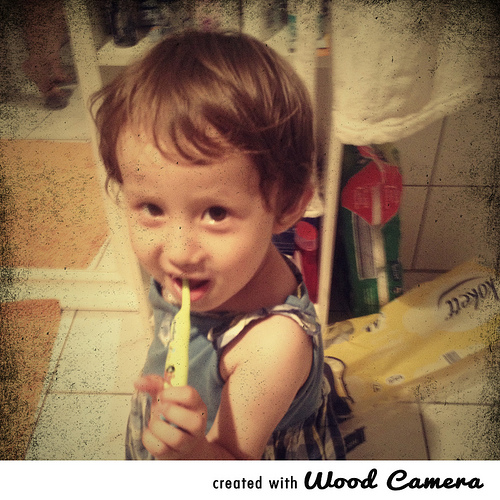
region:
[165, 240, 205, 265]
The nose of the child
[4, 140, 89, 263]
A rug on the floor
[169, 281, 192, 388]
A toothbrush in the child's mouth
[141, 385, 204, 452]
The left hand of the child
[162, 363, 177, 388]
A cartoon character on the toothbrush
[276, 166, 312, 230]
The left ear of the child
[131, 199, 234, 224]
The eyes of the child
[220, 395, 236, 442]
A shadow on the child's arm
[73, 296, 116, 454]
The floor is tiled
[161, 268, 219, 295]
The mouth of the child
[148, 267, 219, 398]
A yellow toothbrush in the girl's mouth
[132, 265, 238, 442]
The girl is holding a yellow toothbrush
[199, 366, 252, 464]
A small shadow on the girl's arm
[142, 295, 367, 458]
A blue and white dress on the girl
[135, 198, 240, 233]
The small girl's brown eyes are open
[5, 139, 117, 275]
Small orange rug behind the girl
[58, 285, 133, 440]
A white tile floor beneath the young girl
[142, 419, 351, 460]
A checkered pattern on the blue and white dress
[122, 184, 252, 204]
The girl's eyebrows can hardly be seen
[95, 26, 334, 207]
The girl's hair is short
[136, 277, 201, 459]
yellow tooth brush in hand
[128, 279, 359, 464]
blue cotton and denim dress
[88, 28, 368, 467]
girl brushing teeth in bathroom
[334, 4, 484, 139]
white towel on rack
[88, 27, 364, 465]
girl standing in bathroom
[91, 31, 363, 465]
girl wearing blue dress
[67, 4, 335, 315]
white plastic shelf in bathroom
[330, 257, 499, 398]
yellow bag on floor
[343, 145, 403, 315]
green bag on floor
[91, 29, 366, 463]
girl holding yellow toothbrush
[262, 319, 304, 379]
part of a shoulder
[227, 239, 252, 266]
part of a cheek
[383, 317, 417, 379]
part of a paper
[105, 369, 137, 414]
part of a floor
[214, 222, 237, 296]
part of a cheek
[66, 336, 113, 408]
part of a floor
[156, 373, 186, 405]
part of a finger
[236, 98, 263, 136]
hair of a kid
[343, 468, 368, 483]
[part of a graphic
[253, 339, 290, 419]
part of a shoiulder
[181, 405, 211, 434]
part of a finger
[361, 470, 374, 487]
part of a letter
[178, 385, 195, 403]
part of a finger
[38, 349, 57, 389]
edge of a path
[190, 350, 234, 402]
part of a cloth